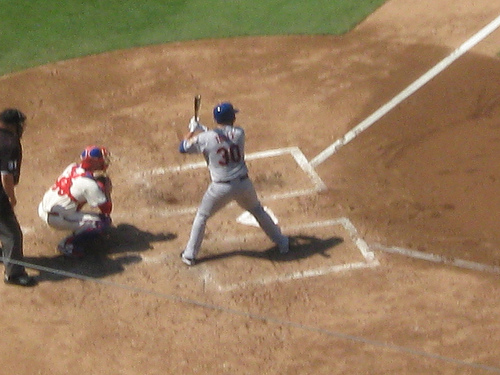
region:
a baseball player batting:
[179, 90, 290, 269]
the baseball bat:
[191, 93, 205, 123]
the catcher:
[36, 138, 121, 263]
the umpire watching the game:
[1, 108, 45, 289]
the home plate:
[238, 204, 281, 229]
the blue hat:
[211, 101, 239, 122]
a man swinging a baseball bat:
[177, 90, 294, 267]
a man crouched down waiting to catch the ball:
[38, 143, 122, 258]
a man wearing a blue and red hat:
[36, 142, 121, 260]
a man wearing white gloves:
[177, 93, 294, 257]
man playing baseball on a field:
[3, 80, 355, 315]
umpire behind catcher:
[0, 100, 131, 310]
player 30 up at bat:
[162, 90, 292, 265]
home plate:
[232, 192, 279, 232]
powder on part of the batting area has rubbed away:
[130, 126, 382, 277]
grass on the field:
[0, 5, 410, 85]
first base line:
[388, 207, 493, 283]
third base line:
[310, 2, 496, 167]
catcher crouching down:
[36, 135, 132, 261]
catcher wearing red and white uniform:
[40, 142, 117, 260]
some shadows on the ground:
[12, 215, 178, 284]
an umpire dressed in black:
[0, 109, 44, 293]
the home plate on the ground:
[235, 198, 282, 234]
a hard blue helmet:
[211, 100, 244, 125]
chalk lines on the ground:
[193, 128, 345, 203]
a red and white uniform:
[38, 144, 123, 248]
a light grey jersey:
[180, 122, 253, 184]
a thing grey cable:
[12, 246, 299, 338]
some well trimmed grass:
[0, 0, 358, 46]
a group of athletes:
[1, 96, 306, 283]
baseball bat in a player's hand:
[192, 92, 203, 125]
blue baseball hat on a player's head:
[210, 100, 239, 116]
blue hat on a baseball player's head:
[211, 102, 239, 119]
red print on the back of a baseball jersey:
[213, 128, 242, 165]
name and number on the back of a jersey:
[213, 130, 243, 169]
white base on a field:
[234, 203, 280, 227]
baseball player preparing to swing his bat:
[179, 92, 290, 267]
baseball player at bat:
[176, 92, 291, 267]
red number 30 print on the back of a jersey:
[216, 143, 243, 167]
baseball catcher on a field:
[36, 143, 115, 256]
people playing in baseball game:
[27, 25, 439, 344]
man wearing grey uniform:
[178, 123, 285, 257]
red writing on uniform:
[206, 129, 253, 178]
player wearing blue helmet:
[210, 102, 245, 124]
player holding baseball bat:
[176, 85, 216, 141]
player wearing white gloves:
[180, 110, 210, 140]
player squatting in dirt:
[32, 158, 123, 255]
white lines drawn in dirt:
[275, 106, 450, 284]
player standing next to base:
[170, 86, 303, 275]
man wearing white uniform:
[35, 135, 116, 244]